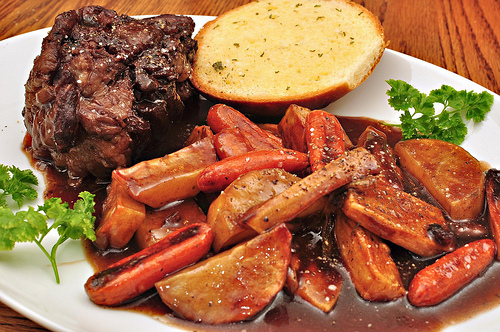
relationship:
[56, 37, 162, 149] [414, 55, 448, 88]
meat on plate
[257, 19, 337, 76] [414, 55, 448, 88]
bun on plate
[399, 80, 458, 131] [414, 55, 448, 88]
leaves on plate